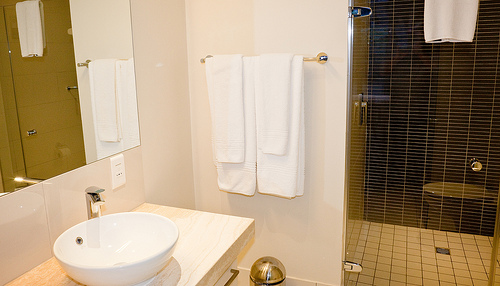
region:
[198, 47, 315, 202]
TOWELS HANGING ON TOWEL RACK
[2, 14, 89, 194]
REFLECTION OF LOCKERS IN MIRROR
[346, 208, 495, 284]
SQUARE TILES ON FLOOR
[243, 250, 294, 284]
WASTE BASKER IS GOLD TONED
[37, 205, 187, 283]
BASIN SITS ON COUNTER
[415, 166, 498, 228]
COMMODE IS BEHIND WIRE BARRIER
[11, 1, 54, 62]
TOWEL HANGING AT TOP OF LOCKER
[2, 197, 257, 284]
RESTROOM COUNTER MADE OF WOODEN MATERIAL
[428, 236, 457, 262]
DRAIN ON TILE FLOOR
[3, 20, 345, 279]
WALLS ARE A CREAM COLOR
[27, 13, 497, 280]
a bathroom area in a building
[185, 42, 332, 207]
towels on a rack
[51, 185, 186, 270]
a unique sink for washing up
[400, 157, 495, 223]
a toilet seat in the bathroom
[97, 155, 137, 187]
an electric wall outlet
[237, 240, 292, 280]
a metal container in the bathroom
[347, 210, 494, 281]
tan tiles on the floor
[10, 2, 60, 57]
a white towel haning up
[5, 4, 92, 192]
a mirror in the bathroom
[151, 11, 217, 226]
tan colored walls in the bathroom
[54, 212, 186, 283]
White sink on the vanity top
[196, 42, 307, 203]
White towels on the towel bar.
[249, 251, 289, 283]
Gold colored trash can.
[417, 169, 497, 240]
toilet reflected in the glass.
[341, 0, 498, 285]
glass door on the shower.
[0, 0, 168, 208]
Mirror on the wall.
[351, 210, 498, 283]
White tile on the floor.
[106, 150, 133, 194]
White plug in on the wall.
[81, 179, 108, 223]
Faucet over the sink.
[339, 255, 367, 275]
Silver colored hinge on the door.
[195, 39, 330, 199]
white towels on a towel rack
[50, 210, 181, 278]
the white basin of a sink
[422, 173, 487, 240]
the reflection of the toilet in the shower door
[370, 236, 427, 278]
white tiles on the shower floor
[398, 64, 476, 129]
black tiles on the shower wall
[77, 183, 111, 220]
a metal water faucet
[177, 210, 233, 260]
a light marble counter top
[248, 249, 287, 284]
the reflective top of a garbage can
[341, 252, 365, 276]
the hinge on a shower door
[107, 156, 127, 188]
a power outlet on the wall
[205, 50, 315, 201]
Folded white towels hanging on rack.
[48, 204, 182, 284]
White sink on top of bathroom vanity.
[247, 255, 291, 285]
Top of trash can in bathroom.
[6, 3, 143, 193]
Edge of mirror mounted over sink.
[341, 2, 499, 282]
Door to shower stall.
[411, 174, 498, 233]
Reflection of commode in shower door.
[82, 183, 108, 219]
Faucet over white sink.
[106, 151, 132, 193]
Electrical outlet on wall next to sink.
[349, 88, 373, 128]
Handle to shower door.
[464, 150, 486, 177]
Reflection of door knob in shower door.